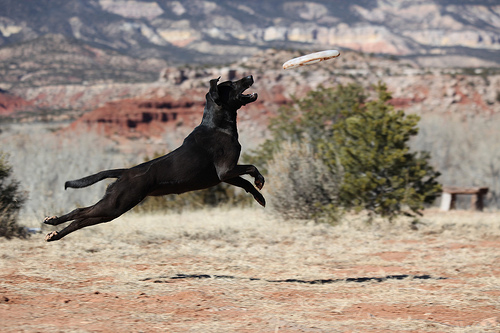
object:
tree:
[130, 150, 255, 215]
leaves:
[388, 154, 417, 180]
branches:
[370, 83, 420, 157]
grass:
[0, 208, 350, 259]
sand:
[22, 246, 499, 331]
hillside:
[0, 0, 499, 72]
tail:
[64, 168, 127, 191]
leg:
[46, 188, 140, 243]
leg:
[43, 195, 103, 226]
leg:
[232, 164, 265, 190]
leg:
[218, 166, 267, 207]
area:
[0, 189, 494, 330]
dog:
[41, 74, 266, 242]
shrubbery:
[238, 73, 439, 231]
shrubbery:
[1, 151, 41, 241]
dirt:
[0, 232, 499, 332]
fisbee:
[282, 49, 340, 70]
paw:
[46, 231, 57, 242]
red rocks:
[57, 89, 205, 136]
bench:
[436, 186, 488, 212]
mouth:
[240, 82, 257, 98]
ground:
[0, 225, 499, 332]